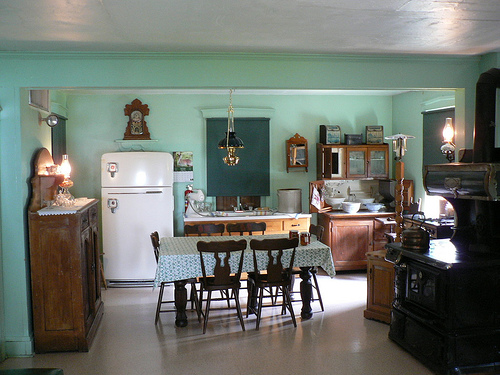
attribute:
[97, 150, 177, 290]
refrigerator — white, old 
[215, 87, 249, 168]
chandelier — gold, black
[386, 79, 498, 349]
stove — old fashioned, black, wood burning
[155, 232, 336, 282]
tablecloth — white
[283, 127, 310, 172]
mirror — wooden, decorative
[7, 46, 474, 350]
wall — light, blue, painted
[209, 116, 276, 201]
shade — dark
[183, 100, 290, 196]
blind — dark green, window, partially-closed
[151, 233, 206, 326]
chair — wooden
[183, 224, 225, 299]
chair — wooden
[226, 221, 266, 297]
chair — wooden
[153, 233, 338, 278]
cloth — white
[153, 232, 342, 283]
cloth — white, patterned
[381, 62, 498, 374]
stove — large, black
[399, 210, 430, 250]
kettle — copper, tea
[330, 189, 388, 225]
bowls — white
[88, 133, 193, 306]
refrigerator — white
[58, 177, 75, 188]
oil — orange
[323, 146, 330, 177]
door — open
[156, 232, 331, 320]
table — small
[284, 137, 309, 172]
mirror — wood-framed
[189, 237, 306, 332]
chairs — Brown, wooden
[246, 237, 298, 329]
chair — wooden, dark brown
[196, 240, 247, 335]
chair — wooden, dark brown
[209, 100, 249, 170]
fixture — light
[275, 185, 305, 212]
pot — large, silver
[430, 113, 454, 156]
lamp — lit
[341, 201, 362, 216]
bowl — white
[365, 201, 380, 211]
bowl — white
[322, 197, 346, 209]
bowl — white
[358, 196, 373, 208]
bowl — white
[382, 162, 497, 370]
stove — wood, antique, black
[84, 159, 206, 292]
fridge — white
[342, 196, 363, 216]
bowl — white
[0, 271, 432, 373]
floor — white, linoleum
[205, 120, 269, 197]
shade — green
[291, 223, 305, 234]
lids — white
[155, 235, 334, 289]
dots — blue